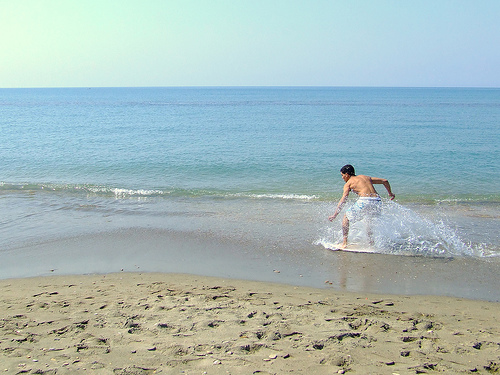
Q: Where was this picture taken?
A: On the beach.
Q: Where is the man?
A: At the beach.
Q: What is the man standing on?
A: Skimboard.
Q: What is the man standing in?
A: Water.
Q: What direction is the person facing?
A: Left.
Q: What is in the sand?
A: Footprints.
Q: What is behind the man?
A: Water splash.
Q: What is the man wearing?
A: White shorts.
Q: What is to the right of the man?
A: The ocean.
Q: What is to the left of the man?
A: Sand.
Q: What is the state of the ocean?
A: Calm.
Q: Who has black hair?
A: The surfer.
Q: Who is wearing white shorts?
A: The surfer.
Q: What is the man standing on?
A: A surfboard.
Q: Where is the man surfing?
A: The ocean.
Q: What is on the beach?
A: Sand.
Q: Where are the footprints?
A: In the sand.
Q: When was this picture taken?
A: Daytime.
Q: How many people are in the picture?
A: One.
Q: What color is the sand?
A: Brown.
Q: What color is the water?
A: Blue.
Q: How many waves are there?
A: One.